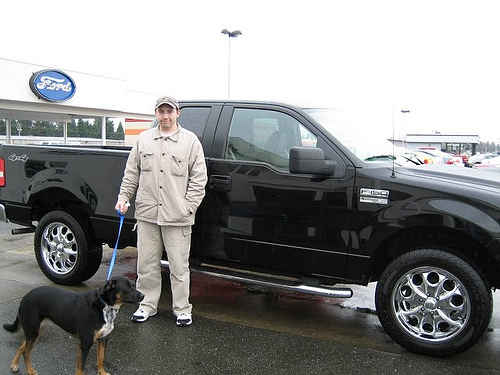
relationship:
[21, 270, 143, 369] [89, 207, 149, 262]
dog on leash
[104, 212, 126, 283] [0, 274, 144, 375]
leash for dog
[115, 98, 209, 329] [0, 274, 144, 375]
man with dog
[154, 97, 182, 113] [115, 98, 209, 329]
hat on man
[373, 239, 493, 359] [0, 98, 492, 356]
rims on truck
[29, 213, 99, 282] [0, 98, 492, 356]
tire on truck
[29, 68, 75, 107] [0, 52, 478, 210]
logo on building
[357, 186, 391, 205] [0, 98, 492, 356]
emblems of truck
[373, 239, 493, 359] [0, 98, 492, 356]
rims of truck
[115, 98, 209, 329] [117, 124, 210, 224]
man wearing jacket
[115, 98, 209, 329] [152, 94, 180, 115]
man wearing hat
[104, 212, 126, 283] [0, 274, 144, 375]
leash on dog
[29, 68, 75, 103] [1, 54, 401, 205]
logo on building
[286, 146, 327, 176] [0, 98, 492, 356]
mirror of truck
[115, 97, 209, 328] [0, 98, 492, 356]
man standing in front of truck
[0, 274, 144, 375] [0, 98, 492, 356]
dog standing in front of truck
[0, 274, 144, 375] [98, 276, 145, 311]
dog has head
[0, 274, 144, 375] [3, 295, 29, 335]
dog has tail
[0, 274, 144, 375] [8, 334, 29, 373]
dog has leg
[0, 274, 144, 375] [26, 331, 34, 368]
dog has leg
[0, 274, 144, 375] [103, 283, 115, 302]
dog has ear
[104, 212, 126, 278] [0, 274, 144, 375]
leash for dog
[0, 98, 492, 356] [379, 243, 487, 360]
truck has wheel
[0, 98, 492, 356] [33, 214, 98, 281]
truck has wheel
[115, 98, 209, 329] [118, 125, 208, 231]
man with jacket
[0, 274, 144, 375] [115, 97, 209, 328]
dog next to a man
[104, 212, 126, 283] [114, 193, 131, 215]
leash in a man's hand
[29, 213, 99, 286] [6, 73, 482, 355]
tire on a vehicle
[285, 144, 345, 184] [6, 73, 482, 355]
mirror on a vehicle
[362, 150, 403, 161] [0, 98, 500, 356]
windshield wiper on a truck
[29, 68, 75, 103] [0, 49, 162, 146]
logo on a building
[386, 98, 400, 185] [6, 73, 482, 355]
antenna on a vehicle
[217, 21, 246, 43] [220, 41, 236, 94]
lights on a pole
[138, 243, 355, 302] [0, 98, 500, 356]
side step on truck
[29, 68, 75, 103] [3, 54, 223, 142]
logo on building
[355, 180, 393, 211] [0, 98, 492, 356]
emblems on truck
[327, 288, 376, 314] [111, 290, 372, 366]
puddle on ground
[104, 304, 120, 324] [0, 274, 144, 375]
spots on dog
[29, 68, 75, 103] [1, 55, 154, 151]
logo on building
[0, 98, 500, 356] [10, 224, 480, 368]
truck in parking lot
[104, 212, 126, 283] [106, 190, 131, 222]
leash in man's hand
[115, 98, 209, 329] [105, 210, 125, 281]
man holding leash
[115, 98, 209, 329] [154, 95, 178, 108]
man wearing hat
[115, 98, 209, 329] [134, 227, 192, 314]
man wearing pants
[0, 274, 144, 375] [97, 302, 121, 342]
dog has patch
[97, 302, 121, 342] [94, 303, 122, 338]
patch on area